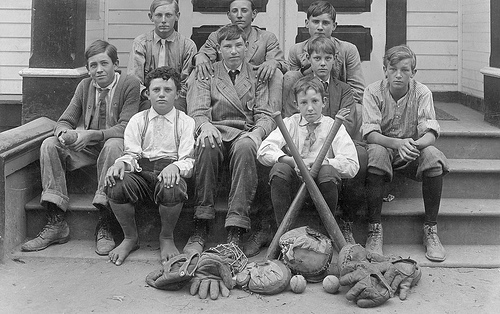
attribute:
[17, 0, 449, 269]
group — boys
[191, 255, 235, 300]
mitt — catcher's 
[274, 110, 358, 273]
bats — wooden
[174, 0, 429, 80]
door — White 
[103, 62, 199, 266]
kid — in foreground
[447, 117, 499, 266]
stairs —  empty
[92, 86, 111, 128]
tie — long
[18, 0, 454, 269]
boys — young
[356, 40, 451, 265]
kid — in foreground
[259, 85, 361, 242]
kid — in foreground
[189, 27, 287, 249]
kid — in foreground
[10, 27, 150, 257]
kid — in foreground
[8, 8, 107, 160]
column — Black 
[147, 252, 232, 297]
gloves — baseball 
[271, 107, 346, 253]
bat — crossed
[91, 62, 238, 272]
boy — young, barefoot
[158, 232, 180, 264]
foot — boy's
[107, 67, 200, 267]
boy — shoeless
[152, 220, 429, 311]
gear — baseball gear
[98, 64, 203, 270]
boy — shoeless